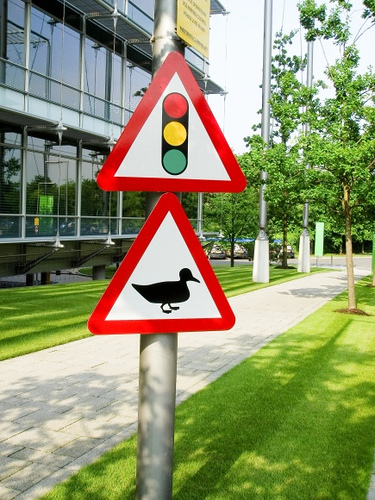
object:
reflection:
[33, 186, 60, 229]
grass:
[49, 192, 55, 209]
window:
[23, 132, 77, 232]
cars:
[201, 232, 297, 261]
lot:
[197, 215, 370, 265]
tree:
[242, 110, 360, 229]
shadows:
[10, 292, 373, 497]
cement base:
[251, 238, 270, 284]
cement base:
[296, 235, 311, 274]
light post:
[256, 1, 273, 240]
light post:
[301, 0, 316, 235]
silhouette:
[131, 267, 201, 313]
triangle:
[85, 192, 235, 331]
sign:
[88, 191, 234, 332]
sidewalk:
[3, 265, 369, 496]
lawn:
[2, 263, 374, 498]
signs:
[46, 29, 327, 480]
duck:
[128, 264, 201, 309]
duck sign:
[83, 192, 238, 335]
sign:
[178, 4, 216, 66]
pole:
[128, 335, 182, 495]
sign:
[104, 94, 250, 210]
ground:
[106, 238, 373, 475]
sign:
[91, 71, 268, 207]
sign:
[94, 199, 234, 331]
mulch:
[333, 305, 369, 316]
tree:
[271, 45, 374, 309]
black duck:
[132, 266, 200, 312]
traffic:
[141, 77, 203, 200]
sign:
[75, 190, 247, 366]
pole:
[128, 2, 191, 498]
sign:
[96, 45, 254, 195]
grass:
[87, 296, 361, 492]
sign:
[82, 193, 240, 340]